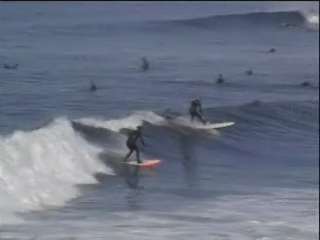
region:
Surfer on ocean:
[114, 120, 162, 174]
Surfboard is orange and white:
[112, 153, 164, 169]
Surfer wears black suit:
[119, 117, 149, 167]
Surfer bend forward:
[120, 119, 149, 167]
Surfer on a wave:
[184, 89, 208, 128]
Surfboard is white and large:
[184, 117, 237, 130]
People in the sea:
[0, 20, 313, 95]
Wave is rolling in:
[5, 94, 316, 233]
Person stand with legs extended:
[116, 119, 159, 173]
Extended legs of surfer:
[180, 91, 215, 132]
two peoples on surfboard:
[116, 87, 237, 183]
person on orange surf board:
[105, 118, 169, 177]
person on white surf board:
[177, 90, 237, 137]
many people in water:
[14, 36, 312, 107]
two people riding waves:
[5, 105, 260, 180]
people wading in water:
[10, 48, 306, 146]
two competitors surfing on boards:
[93, 77, 263, 171]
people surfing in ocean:
[10, 49, 292, 186]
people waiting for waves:
[14, 53, 203, 100]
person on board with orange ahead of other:
[107, 84, 265, 196]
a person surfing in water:
[114, 120, 162, 174]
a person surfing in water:
[173, 88, 232, 136]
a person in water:
[77, 72, 97, 101]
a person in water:
[135, 51, 155, 79]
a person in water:
[210, 63, 233, 100]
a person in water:
[243, 57, 263, 93]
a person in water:
[265, 42, 279, 58]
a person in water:
[298, 68, 316, 107]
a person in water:
[117, 117, 147, 168]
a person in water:
[181, 75, 215, 138]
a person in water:
[178, 90, 209, 125]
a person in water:
[84, 74, 102, 102]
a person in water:
[210, 66, 226, 85]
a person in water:
[238, 60, 258, 80]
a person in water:
[293, 75, 312, 97]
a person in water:
[0, 50, 19, 85]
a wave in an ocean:
[2, 113, 191, 216]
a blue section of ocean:
[0, 0, 319, 239]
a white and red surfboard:
[122, 155, 164, 166]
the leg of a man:
[131, 146, 143, 162]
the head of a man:
[134, 123, 145, 132]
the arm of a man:
[137, 132, 147, 147]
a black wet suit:
[121, 123, 151, 162]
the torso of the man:
[124, 130, 147, 144]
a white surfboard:
[193, 119, 233, 134]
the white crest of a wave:
[0, 106, 172, 230]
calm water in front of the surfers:
[92, 125, 319, 237]